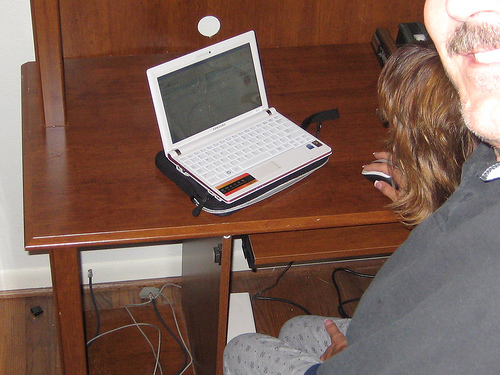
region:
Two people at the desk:
[98, 42, 492, 344]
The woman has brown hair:
[324, 53, 468, 232]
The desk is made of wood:
[26, 111, 141, 218]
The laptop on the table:
[138, 27, 338, 224]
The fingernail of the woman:
[366, 171, 387, 193]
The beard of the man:
[442, 16, 499, 63]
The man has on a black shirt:
[361, 143, 498, 367]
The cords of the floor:
[82, 270, 192, 372]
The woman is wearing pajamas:
[213, 298, 350, 372]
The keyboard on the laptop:
[183, 116, 313, 184]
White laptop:
[126, 30, 341, 217]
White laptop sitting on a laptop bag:
[127, 32, 337, 215]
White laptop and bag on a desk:
[134, 26, 338, 221]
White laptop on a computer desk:
[142, 30, 345, 227]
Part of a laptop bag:
[147, 150, 247, 219]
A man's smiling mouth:
[429, 13, 497, 84]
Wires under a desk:
[126, 283, 191, 374]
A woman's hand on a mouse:
[355, 146, 400, 197]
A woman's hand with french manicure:
[359, 136, 409, 202]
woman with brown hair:
[406, 88, 428, 125]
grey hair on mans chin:
[458, 105, 480, 138]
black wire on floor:
[266, 273, 287, 297]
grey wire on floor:
[136, 281, 160, 305]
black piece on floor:
[24, 301, 46, 321]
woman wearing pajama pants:
[258, 343, 282, 363]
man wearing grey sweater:
[397, 271, 478, 301]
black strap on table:
[306, 105, 342, 124]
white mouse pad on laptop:
[251, 164, 279, 178]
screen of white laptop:
[128, 54, 273, 119]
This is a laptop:
[126, 46, 337, 192]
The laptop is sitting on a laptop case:
[125, 29, 350, 206]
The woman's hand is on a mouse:
[357, 133, 419, 209]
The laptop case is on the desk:
[136, 123, 343, 216]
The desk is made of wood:
[23, 7, 423, 356]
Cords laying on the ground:
[85, 274, 197, 370]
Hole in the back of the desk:
[194, 6, 224, 38]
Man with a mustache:
[436, 18, 496, 50]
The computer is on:
[156, 41, 276, 140]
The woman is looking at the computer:
[137, 47, 453, 220]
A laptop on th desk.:
[116, 38, 344, 197]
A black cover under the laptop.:
[146, 129, 222, 222]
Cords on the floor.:
[143, 288, 196, 373]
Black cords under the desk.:
[253, 267, 390, 310]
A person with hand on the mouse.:
[363, 143, 410, 208]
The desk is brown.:
[16, 41, 136, 216]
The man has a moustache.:
[449, 26, 491, 62]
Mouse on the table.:
[368, 143, 396, 194]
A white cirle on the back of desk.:
[184, 3, 243, 43]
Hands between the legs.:
[317, 315, 374, 372]